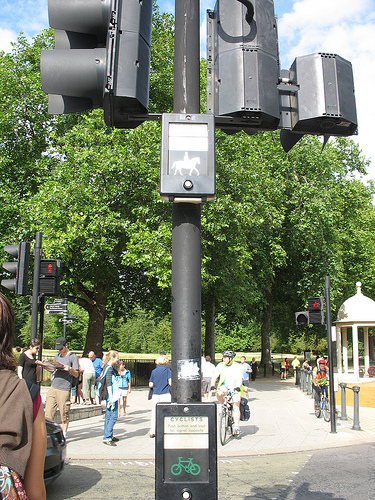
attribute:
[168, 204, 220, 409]
pole — black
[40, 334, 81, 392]
guy — reading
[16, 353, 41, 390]
top — black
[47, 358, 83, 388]
teeshirt — gray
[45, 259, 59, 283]
light — red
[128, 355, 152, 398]
fence — black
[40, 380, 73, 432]
trouser — brown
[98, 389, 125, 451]
woman — standing